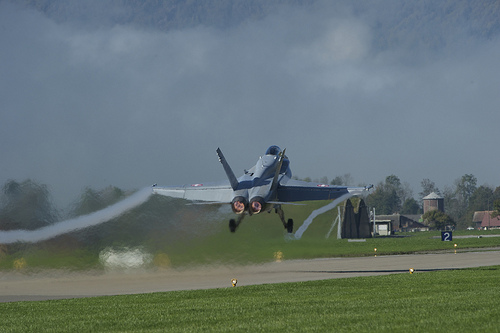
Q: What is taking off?
A: Jet.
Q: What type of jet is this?
A: Fighter.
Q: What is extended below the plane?
A: Landing gear.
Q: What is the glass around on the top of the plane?
A: Cockpit.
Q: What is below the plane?
A: Runway.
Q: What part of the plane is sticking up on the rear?
A: Tail fins.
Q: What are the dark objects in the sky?
A: Clouds.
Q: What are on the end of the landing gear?
A: Wheels.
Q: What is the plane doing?
A: Taking off the runway.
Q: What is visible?
A: The grass.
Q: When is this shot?
A: Daytime.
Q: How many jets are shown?
A: 1.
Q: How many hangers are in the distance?
A: 2.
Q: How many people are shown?
A: 0.